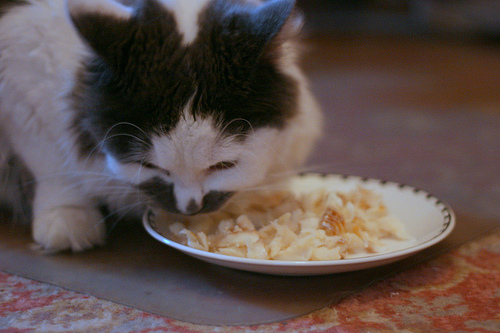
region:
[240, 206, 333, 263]
white cat food on a plate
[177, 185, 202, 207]
a white cats nose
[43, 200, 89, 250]
the paw of the cat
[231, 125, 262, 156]
whiskers on the white and black cat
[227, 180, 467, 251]
a white plate with cat food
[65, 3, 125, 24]
the cats grey ear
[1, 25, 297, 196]
a grey and white cat eating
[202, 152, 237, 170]
the cats eyeball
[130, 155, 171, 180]
the black and white cats eye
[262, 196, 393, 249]
it is cat food in a plate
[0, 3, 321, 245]
Small bunny with black and white fur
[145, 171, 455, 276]
Plate of food for the bunny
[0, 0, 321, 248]
The bunny is currently eating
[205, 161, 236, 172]
Left eye of bunny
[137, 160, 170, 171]
Right eye of bunny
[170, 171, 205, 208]
Nose of the bunny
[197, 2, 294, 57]
Section of the left ear of the bunny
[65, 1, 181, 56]
Section of the right ear of the bunny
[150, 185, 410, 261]
Food on the plate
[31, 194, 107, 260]
Right arm of the bunny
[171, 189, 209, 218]
Black dot on cats nose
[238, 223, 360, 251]
Fish on a plate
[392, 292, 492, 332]
Red and orange carpet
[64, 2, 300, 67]
Two ears on cat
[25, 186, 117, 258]
kitten's right paw on floor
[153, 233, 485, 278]
Cat's white food dish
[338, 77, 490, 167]
Matt to protect carpet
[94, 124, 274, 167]
White whiskers above eyes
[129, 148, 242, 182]
Two black eyes on cat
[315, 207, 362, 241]
Big chunk of fish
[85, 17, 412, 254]
the cat is eating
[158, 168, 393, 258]
the food is on the plate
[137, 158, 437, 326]
the plate is on the ground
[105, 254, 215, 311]
the ground is brown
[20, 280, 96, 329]
the carpet is printed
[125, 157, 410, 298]
the plate is white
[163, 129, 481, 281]
the plate is round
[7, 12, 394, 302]
the cat's body is white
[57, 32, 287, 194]
the cat's face is black and white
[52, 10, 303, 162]
cat's ears are black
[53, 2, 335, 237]
a black and white cat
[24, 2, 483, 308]
a cat eating from a dish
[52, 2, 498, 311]
a black and white cat eating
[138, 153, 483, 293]
a dish with pet food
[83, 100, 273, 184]
a cat's eyes and whiskers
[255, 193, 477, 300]
cat food on a plate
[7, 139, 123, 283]
a cat's front paw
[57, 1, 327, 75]
a cat's ears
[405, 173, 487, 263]
the design on the edge of a dish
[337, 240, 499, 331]
a red colored table cloth